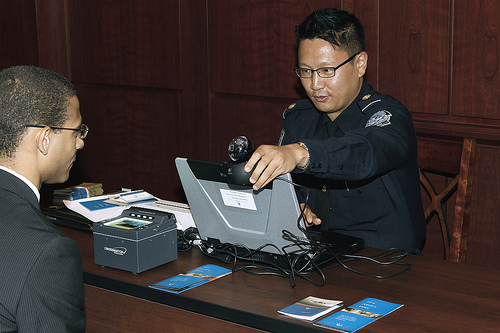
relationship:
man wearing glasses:
[1, 72, 87, 331] [25, 123, 88, 137]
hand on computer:
[245, 142, 311, 189] [168, 156, 365, 268]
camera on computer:
[228, 135, 250, 160] [168, 156, 365, 268]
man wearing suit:
[1, 72, 87, 331] [1, 169, 84, 332]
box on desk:
[93, 206, 179, 272] [45, 182, 498, 332]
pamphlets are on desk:
[277, 287, 404, 332] [45, 182, 498, 332]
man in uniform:
[243, 7, 427, 254] [278, 86, 428, 249]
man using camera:
[243, 7, 427, 254] [228, 135, 250, 160]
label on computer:
[218, 188, 258, 213] [168, 156, 365, 268]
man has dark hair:
[243, 7, 427, 254] [298, 10, 365, 61]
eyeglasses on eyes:
[295, 51, 363, 77] [300, 66, 331, 75]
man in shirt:
[260, 6, 430, 254] [278, 82, 428, 254]